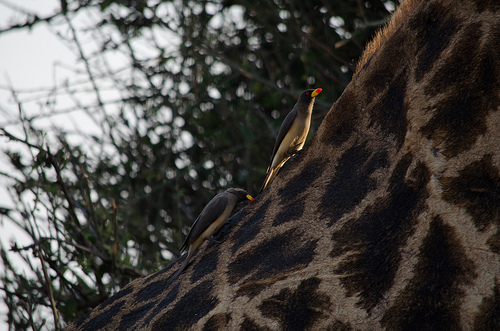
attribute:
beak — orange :
[244, 190, 256, 202]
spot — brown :
[272, 151, 326, 222]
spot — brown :
[222, 225, 320, 299]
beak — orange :
[307, 90, 324, 102]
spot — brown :
[244, 312, 268, 329]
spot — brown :
[304, 115, 396, 230]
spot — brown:
[376, 210, 479, 329]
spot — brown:
[465, 286, 497, 327]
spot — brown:
[425, 145, 498, 235]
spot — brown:
[254, 271, 334, 328]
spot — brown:
[386, 209, 476, 329]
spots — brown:
[92, 18, 478, 324]